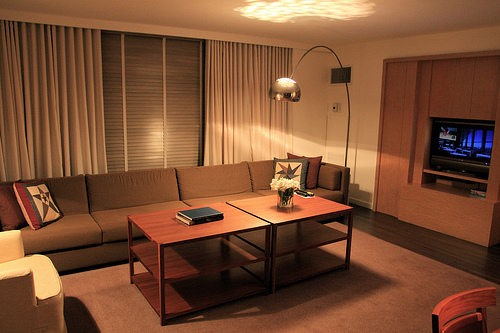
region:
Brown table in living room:
[126, 198, 268, 327]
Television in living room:
[420, 112, 491, 172]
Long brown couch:
[3, 156, 353, 273]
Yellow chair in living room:
[1, 227, 68, 331]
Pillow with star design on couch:
[13, 172, 61, 232]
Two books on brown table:
[173, 202, 222, 227]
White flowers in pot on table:
[268, 170, 300, 212]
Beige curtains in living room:
[1, 19, 106, 181]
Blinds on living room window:
[105, 35, 210, 168]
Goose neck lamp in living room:
[270, 43, 358, 195]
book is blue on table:
[142, 196, 244, 253]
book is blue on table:
[162, 179, 219, 262]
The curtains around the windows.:
[25, 41, 265, 149]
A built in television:
[408, 69, 494, 194]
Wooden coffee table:
[121, 202, 378, 319]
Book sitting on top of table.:
[143, 205, 227, 232]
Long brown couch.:
[10, 158, 339, 201]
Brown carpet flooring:
[367, 277, 410, 331]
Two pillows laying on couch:
[282, 140, 331, 201]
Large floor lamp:
[246, 6, 373, 150]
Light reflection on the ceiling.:
[229, 2, 375, 34]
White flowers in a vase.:
[265, 155, 302, 220]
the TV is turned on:
[409, 93, 498, 227]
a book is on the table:
[110, 191, 285, 325]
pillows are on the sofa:
[5, 147, 364, 307]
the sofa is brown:
[0, 147, 352, 274]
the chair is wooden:
[419, 273, 496, 330]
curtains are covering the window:
[2, 12, 304, 231]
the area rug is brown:
[40, 211, 498, 331]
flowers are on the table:
[242, 150, 340, 292]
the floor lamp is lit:
[266, 40, 386, 246]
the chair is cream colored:
[0, 218, 80, 331]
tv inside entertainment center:
[430, 120, 492, 172]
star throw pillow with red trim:
[12, 176, 65, 228]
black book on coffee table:
[177, 203, 222, 223]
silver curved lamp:
[269, 42, 348, 169]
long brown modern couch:
[3, 159, 350, 274]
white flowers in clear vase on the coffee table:
[270, 176, 295, 208]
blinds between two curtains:
[100, 31, 202, 168]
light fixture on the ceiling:
[235, 3, 374, 25]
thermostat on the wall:
[331, 102, 342, 113]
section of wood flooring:
[336, 199, 497, 284]